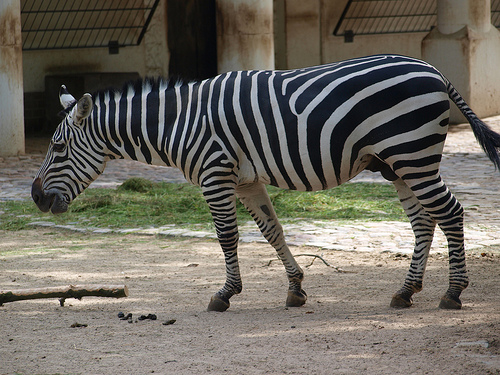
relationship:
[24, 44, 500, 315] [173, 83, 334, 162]
zebra has stripes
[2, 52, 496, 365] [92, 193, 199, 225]
area of grass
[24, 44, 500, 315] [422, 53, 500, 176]
zebra has a tail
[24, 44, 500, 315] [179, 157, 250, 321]
zebra has a leg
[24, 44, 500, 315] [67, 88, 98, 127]
zebra has ear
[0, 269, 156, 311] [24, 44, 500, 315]
branch under zebra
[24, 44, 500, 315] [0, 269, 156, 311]
zebra over branch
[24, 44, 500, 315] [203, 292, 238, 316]
zebra has hoof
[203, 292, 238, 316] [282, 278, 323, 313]
hoof next to hoof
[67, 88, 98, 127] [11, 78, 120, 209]
ear on top of head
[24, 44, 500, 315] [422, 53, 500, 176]
zebra has tail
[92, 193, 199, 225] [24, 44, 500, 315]
grass behind zebra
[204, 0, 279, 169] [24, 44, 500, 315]
cloumn behind zebra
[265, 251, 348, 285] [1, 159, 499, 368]
twig on top of ground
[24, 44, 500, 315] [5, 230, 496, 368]
zebra on sand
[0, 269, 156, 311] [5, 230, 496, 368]
branch on top of sand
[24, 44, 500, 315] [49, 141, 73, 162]
zebra has eye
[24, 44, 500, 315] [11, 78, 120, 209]
zebra has head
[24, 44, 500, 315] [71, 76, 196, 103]
zebra has hair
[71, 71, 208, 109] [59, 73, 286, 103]
hair on top of zebra's back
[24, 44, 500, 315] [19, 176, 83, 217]
zebra has mouth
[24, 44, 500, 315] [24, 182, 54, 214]
zebra has nose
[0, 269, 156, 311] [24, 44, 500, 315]
branch lying next to zebra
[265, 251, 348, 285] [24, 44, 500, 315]
twig next to zebra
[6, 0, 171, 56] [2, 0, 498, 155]
rail on side of building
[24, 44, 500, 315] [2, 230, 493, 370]
zebra standing in dirt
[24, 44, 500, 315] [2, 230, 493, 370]
zebra standing on dirt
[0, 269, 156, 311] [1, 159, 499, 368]
branch lying on ground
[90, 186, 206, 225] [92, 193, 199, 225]
patch of grass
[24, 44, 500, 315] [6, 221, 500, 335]
zebra on top of road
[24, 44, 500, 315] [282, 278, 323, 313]
zebra has hoof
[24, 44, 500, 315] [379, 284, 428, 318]
zebra has hoof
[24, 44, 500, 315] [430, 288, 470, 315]
zebra has hoof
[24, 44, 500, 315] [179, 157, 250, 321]
zebra has leg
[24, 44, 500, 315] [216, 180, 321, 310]
zebra has leg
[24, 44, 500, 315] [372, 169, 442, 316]
zebra has leg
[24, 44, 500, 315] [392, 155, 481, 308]
zebra has leg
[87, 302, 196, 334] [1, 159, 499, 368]
rocks on top of ground